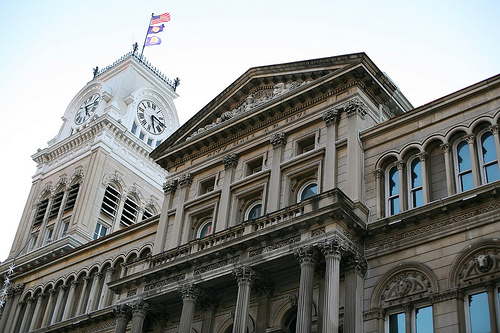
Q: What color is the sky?
A: White and blue.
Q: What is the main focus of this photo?
A: An old building.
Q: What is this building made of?
A: Concrete.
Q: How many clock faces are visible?
A: Two.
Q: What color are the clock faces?
A: White.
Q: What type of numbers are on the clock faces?
A: Roman numerals.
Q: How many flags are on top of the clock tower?
A: Three.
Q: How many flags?
A: Three.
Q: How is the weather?
A: Clear and sunny.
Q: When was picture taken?
A: 5:15.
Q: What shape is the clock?
A: Round.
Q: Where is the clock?
A: In the tower.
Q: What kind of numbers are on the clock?
A: Roman Numerals.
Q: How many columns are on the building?
A: Six.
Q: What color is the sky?
A: Blue.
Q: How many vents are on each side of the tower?
A: Three.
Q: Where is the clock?
A: White tower.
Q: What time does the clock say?
A: 5:15.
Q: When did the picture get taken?
A: Daytime.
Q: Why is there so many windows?
A: Lots of rooms.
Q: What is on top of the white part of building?
A: Flags.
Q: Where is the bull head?
A: Above window bottom left.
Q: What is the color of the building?
A: Tan.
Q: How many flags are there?
A: 3.